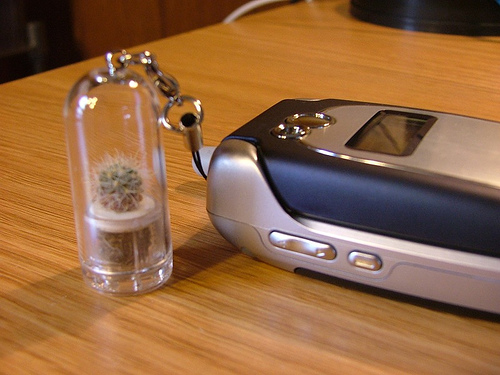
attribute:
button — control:
[267, 233, 337, 260]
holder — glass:
[55, 46, 179, 301]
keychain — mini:
[44, 42, 227, 309]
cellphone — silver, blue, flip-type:
[201, 93, 498, 322]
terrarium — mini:
[62, 69, 179, 281]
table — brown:
[1, 1, 498, 372]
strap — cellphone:
[117, 50, 207, 181]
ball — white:
[81, 148, 154, 210]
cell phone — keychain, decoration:
[206, 100, 498, 325]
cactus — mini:
[89, 159, 145, 214]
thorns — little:
[83, 126, 159, 202]